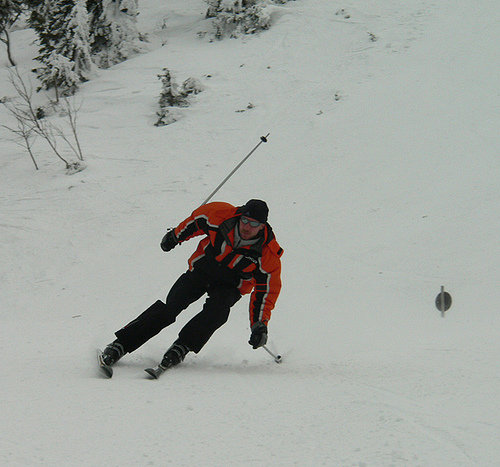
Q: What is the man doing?
A: Skiing.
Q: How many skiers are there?
A: One.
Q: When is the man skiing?
A: Daytime.